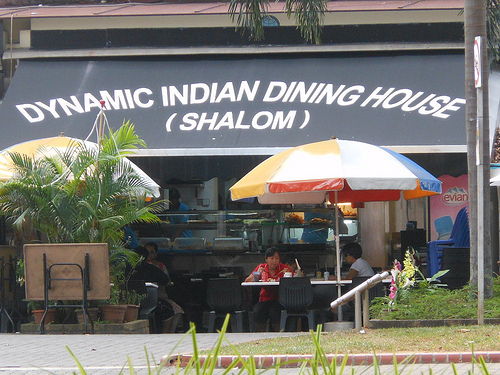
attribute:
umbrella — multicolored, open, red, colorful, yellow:
[226, 136, 444, 204]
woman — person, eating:
[246, 245, 294, 333]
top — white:
[348, 256, 380, 281]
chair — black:
[205, 277, 250, 333]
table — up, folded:
[20, 240, 113, 335]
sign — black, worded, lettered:
[2, 55, 467, 145]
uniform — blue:
[163, 202, 192, 233]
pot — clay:
[100, 304, 127, 323]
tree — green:
[1, 120, 150, 306]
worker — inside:
[159, 186, 193, 244]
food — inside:
[281, 212, 309, 225]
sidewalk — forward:
[1, 332, 300, 375]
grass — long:
[198, 323, 500, 354]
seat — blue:
[426, 203, 470, 281]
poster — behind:
[430, 173, 470, 241]